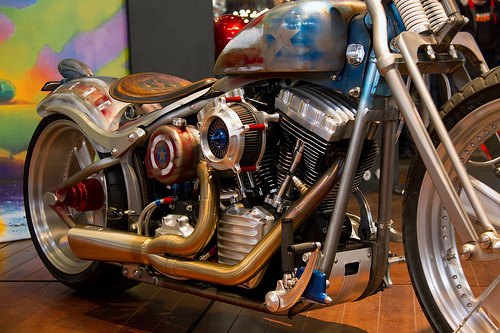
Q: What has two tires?
A: A motorcycle.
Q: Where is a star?
A: On side of motorcycle.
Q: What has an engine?
A: Motorcycle.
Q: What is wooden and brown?
A: The floor.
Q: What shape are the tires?
A: Round.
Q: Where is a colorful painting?
A: On the wall.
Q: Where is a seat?
A: On the motorcycle.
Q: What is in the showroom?
A: Customized Motorcycle.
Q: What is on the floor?
A: Shadow of a motorcycle.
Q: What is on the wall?
A: Painting.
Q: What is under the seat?
A: Engine Block.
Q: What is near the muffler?
A: Rear tire.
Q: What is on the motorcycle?
A: Brown seat.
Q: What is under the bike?
A: Wooden floor.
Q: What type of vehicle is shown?
A: Motorcycle.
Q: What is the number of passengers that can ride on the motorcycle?
A: 1.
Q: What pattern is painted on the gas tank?
A: American flag.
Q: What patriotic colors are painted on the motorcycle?
A: Red, white and blue.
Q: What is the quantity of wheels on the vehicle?
A: 2.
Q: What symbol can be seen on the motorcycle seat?
A: Stars.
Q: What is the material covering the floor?
A: Wood.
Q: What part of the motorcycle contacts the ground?
A: Tires.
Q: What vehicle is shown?
A: Motorcycle.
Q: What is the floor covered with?
A: Brick.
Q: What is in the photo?
A: Motorcycle.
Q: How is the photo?
A: Clear.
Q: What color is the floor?
A: Brown.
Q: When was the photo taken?
A: Daytime.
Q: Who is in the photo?
A: Nobody.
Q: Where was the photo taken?
A: In a store.